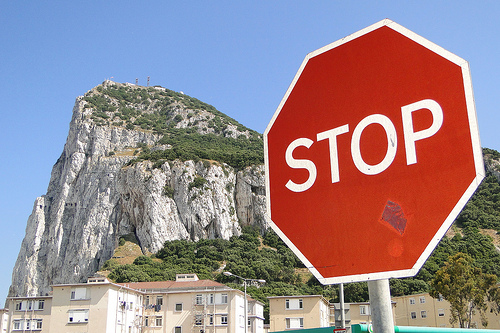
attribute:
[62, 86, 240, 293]
formation — large, rock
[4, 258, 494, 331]
building — large, tan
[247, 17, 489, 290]
sign — red, saying stop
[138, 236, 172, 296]
trees — old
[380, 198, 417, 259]
smudge — stop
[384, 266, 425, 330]
post — metallic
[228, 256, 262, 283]
plants — green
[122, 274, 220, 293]
roof — tops, brown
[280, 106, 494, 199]
white writing — in all caps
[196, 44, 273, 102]
sky — blue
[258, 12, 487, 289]
stop sign — red, white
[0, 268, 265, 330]
building — tan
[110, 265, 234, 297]
roof — brown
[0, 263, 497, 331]
houses — large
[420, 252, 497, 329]
tree — green, yellow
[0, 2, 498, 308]
sky — clear, blue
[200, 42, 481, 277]
stop sign — red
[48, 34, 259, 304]
formation — rock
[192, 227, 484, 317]
wall — light brown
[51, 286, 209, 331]
windows — white